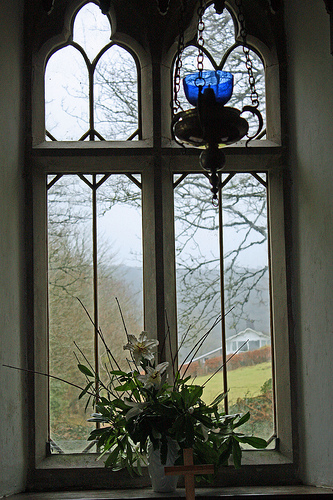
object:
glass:
[182, 72, 234, 104]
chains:
[169, 2, 260, 119]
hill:
[177, 354, 270, 445]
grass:
[183, 361, 273, 411]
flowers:
[124, 332, 160, 367]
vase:
[148, 437, 183, 492]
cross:
[164, 448, 215, 499]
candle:
[189, 69, 225, 104]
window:
[42, 7, 138, 141]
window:
[39, 5, 275, 457]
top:
[41, 5, 140, 142]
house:
[230, 326, 263, 354]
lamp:
[183, 72, 234, 101]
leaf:
[220, 411, 248, 434]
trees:
[52, 267, 135, 447]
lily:
[125, 333, 158, 366]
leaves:
[180, 387, 220, 428]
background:
[48, 173, 279, 454]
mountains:
[92, 264, 270, 362]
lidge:
[15, 482, 329, 499]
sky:
[41, 2, 268, 271]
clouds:
[32, 6, 268, 268]